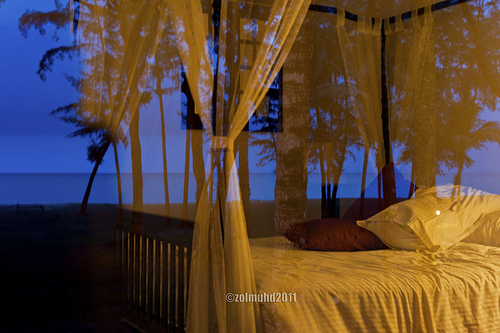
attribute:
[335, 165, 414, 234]
red pillow — small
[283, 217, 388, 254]
pillow — red, small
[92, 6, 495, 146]
canopy — large, white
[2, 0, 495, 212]
sky — blue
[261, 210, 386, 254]
pillow — red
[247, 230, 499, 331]
sheets — white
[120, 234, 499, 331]
sheet — wrinkled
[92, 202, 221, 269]
rail — wooden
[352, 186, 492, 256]
pillow — large, white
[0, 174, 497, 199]
ocean — distant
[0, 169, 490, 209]
water — calm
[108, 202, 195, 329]
wooden footboard — large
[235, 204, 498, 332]
bed — made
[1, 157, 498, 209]
water — still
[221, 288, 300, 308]
watermark — white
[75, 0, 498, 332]
bed — large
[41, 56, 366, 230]
trees — palm 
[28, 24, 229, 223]
sky — dark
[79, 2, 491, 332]
canopy cover — large, white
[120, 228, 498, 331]
comforter — striped